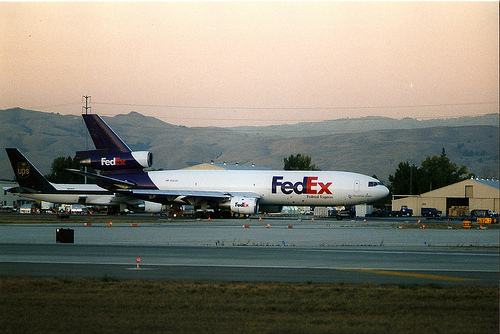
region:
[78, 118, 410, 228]
A plane on the runway.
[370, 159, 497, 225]
A building next to the runway.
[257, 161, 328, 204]
The plane is FedEx.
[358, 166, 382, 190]
Cockpit of the plane.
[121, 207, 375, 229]
Cones on the ground.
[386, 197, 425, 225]
Truck parked in front of the building.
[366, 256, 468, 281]
A yellow line in the runway.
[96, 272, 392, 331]
Grass next to the runway.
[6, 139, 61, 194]
The tail of the wing says UPS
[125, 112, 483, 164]
Mountains in the background.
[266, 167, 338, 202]
company name on side of aircraft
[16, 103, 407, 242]
aircraft parked on runway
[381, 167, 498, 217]
beige building on edge of runway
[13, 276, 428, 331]
green grass growing beside runway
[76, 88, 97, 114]
large metal electric pole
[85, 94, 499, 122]
row of electric lines behind runway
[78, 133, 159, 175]
large jet engine on aircraft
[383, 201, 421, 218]
work truck parked beside building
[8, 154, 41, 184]
company logo on tail fin of aircraft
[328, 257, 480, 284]
yellow line painted on runway pavement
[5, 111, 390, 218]
two airplanes on the tarmac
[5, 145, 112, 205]
the UPS airplane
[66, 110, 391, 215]
the FedEx airplane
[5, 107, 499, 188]
mountains on the horizon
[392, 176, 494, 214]
tan cargo building on the right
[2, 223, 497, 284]
the concrete tarmac and runway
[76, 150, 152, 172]
jet engine on tail of FedEx plane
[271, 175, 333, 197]
red and blue letters on fuselage of plaine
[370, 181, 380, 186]
cockpit windows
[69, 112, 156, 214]
blue tail section of airplane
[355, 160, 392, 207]
cockpit of a plane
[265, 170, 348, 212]
fedex logo of a plane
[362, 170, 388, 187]
window of a plane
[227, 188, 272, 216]
turbine of a plane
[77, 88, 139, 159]
wing of a plane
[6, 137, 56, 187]
wing of a plane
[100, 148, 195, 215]
tail of a plane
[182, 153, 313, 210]
body of a plane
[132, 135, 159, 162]
turbine of a plane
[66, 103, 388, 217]
Airplane on the ground.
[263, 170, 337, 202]
Logo on the plane.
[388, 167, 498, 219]
Building in the background.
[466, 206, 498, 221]
vehicle by the building.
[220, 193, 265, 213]
Engine on the plane.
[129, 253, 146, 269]
Light on the ground.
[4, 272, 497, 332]
Grass covering the ground.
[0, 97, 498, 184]
Mountains in the background.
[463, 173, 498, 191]
Gray roof on the building.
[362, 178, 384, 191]
Windows in the plane.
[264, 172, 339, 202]
the words FedEx on the side of the plane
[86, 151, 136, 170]
the word fedex on the wing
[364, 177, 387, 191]
the cock pit windows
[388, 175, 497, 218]
the tan building by the plane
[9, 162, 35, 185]
the words UPS on the plane's tail